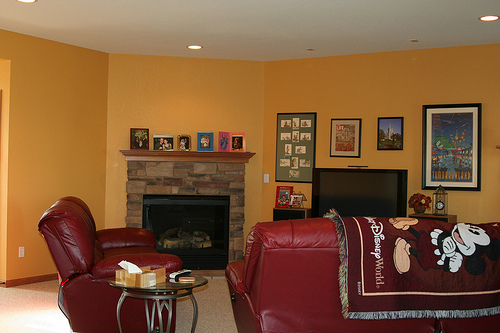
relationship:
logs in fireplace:
[157, 225, 213, 251] [144, 195, 227, 262]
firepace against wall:
[119, 147, 244, 279] [104, 50, 266, 247]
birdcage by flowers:
[432, 182, 450, 214] [406, 186, 437, 221]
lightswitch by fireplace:
[261, 170, 269, 189] [122, 142, 256, 272]